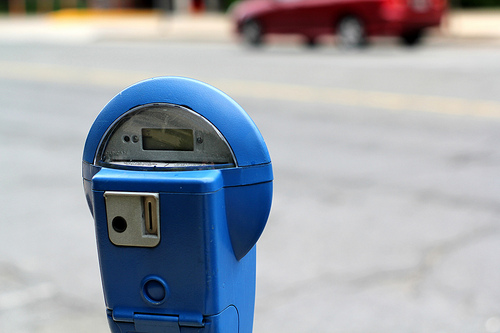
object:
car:
[228, 0, 453, 49]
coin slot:
[143, 197, 157, 235]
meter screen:
[141, 126, 195, 152]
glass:
[91, 103, 236, 163]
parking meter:
[77, 74, 275, 333]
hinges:
[110, 310, 213, 333]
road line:
[277, 79, 499, 116]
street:
[1, 41, 500, 331]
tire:
[336, 15, 373, 51]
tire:
[236, 20, 269, 49]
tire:
[396, 26, 424, 47]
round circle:
[138, 275, 173, 307]